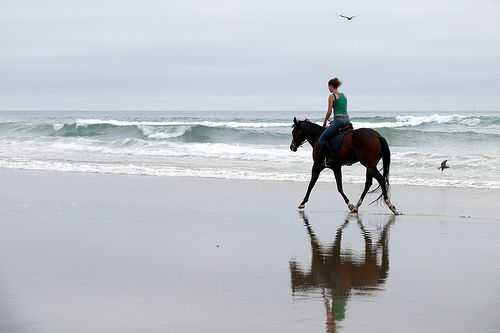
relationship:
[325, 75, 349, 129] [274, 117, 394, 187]
girl riding horse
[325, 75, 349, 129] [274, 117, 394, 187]
girl on horse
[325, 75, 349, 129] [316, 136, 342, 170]
girl wearing boots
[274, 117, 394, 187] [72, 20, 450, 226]
horse at beach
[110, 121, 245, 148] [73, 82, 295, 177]
waves in water